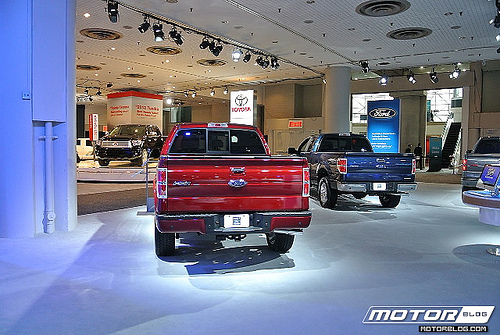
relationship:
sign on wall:
[289, 118, 306, 126] [269, 117, 326, 152]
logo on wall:
[232, 92, 252, 108] [226, 89, 252, 126]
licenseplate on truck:
[222, 210, 249, 228] [139, 96, 310, 269]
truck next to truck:
[151, 120, 313, 258] [302, 132, 398, 217]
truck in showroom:
[151, 120, 313, 258] [48, 27, 426, 314]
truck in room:
[97, 122, 181, 167] [0, 0, 500, 334]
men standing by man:
[399, 141, 428, 173] [401, 137, 416, 177]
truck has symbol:
[155, 122, 310, 257] [229, 178, 247, 189]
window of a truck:
[167, 127, 265, 154] [146, 118, 317, 255]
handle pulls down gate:
[229, 165, 246, 176] [160, 160, 306, 209]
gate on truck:
[160, 160, 306, 209] [151, 116, 320, 274]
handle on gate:
[229, 165, 246, 176] [160, 160, 306, 209]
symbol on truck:
[204, 175, 269, 201] [146, 118, 317, 255]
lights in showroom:
[132, 4, 304, 87] [21, 6, 482, 292]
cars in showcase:
[189, 139, 374, 230] [2, 15, 480, 254]